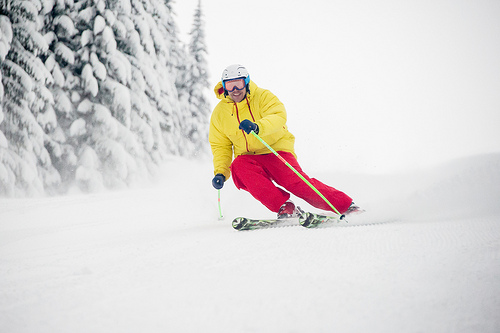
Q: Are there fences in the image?
A: No, there are no fences.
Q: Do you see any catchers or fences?
A: No, there are no fences or catchers.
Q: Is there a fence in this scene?
A: No, there are no fences.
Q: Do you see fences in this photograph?
A: No, there are no fences.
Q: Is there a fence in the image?
A: No, there are no fences.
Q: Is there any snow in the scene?
A: Yes, there is snow.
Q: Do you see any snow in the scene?
A: Yes, there is snow.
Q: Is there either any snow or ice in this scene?
A: Yes, there is snow.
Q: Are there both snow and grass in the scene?
A: No, there is snow but no grass.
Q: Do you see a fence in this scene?
A: No, there are no fences.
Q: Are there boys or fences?
A: No, there are no fences or boys.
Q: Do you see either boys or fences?
A: No, there are no fences or boys.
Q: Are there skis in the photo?
A: Yes, there are skis.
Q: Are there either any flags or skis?
A: Yes, there are skis.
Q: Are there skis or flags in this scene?
A: Yes, there are skis.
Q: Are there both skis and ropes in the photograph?
A: No, there are skis but no ropes.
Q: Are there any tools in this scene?
A: No, there are no tools.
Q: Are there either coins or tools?
A: No, there are no tools or coins.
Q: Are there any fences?
A: No, there are no fences.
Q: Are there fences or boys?
A: No, there are no fences or boys.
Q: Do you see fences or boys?
A: No, there are no fences or boys.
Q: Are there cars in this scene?
A: No, there are no cars.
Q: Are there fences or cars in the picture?
A: No, there are no cars or fences.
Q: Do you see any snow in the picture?
A: Yes, there is snow.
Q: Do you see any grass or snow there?
A: Yes, there is snow.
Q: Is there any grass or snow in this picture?
A: Yes, there is snow.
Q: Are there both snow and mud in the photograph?
A: No, there is snow but no mud.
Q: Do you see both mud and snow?
A: No, there is snow but no mud.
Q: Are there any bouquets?
A: No, there are no bouquets.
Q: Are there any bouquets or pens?
A: No, there are no bouquets or pens.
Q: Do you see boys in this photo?
A: No, there are no boys.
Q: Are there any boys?
A: No, there are no boys.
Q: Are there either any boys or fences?
A: No, there are no boys or fences.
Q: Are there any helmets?
A: Yes, there is a helmet.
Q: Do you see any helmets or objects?
A: Yes, there is a helmet.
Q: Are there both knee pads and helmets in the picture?
A: No, there is a helmet but no knee pads.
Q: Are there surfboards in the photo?
A: No, there are no surfboards.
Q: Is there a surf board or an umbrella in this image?
A: No, there are no surfboards or umbrellas.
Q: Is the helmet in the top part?
A: Yes, the helmet is in the top of the image.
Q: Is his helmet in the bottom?
A: No, the helmet is in the top of the image.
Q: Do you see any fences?
A: No, there are no fences.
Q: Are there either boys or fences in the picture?
A: No, there are no fences or boys.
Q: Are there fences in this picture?
A: No, there are no fences.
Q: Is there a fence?
A: No, there are no fences.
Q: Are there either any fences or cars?
A: No, there are no fences or cars.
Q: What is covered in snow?
A: The tree is covered in snow.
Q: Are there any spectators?
A: No, there are no spectators.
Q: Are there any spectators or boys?
A: No, there are no spectators or boys.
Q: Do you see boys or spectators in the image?
A: No, there are no spectators or boys.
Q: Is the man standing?
A: Yes, the man is standing.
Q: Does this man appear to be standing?
A: Yes, the man is standing.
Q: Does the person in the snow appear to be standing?
A: Yes, the man is standing.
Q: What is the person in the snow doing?
A: The man is standing.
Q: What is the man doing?
A: The man is standing.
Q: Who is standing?
A: The man is standing.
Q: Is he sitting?
A: No, the man is standing.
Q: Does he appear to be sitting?
A: No, the man is standing.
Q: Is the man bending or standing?
A: The man is standing.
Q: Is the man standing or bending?
A: The man is standing.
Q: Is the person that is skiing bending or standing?
A: The man is standing.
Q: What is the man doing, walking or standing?
A: The man is standing.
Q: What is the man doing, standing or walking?
A: The man is standing.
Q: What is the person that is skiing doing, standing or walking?
A: The man is standing.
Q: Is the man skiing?
A: Yes, the man is skiing.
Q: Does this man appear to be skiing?
A: Yes, the man is skiing.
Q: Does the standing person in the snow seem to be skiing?
A: Yes, the man is skiing.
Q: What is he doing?
A: The man is skiing.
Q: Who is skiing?
A: The man is skiing.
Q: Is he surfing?
A: No, the man is skiing.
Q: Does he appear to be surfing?
A: No, the man is skiing.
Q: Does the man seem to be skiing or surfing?
A: The man is skiing.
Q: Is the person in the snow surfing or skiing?
A: The man is skiing.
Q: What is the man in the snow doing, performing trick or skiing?
A: The man is skiing.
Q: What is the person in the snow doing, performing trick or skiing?
A: The man is skiing.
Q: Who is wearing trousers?
A: The man is wearing trousers.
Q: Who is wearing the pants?
A: The man is wearing trousers.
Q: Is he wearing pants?
A: Yes, the man is wearing pants.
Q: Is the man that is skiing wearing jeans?
A: No, the man is wearing pants.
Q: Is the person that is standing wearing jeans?
A: No, the man is wearing pants.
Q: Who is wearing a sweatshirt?
A: The man is wearing a sweatshirt.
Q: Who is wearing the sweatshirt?
A: The man is wearing a sweatshirt.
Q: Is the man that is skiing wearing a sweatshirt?
A: Yes, the man is wearing a sweatshirt.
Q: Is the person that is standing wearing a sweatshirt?
A: Yes, the man is wearing a sweatshirt.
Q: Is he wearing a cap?
A: No, the man is wearing a sweatshirt.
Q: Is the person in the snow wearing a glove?
A: Yes, the man is wearing a glove.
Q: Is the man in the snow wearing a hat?
A: No, the man is wearing a glove.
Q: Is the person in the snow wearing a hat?
A: No, the man is wearing a glove.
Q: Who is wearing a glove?
A: The man is wearing a glove.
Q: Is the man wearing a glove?
A: Yes, the man is wearing a glove.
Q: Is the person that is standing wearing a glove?
A: Yes, the man is wearing a glove.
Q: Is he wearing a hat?
A: No, the man is wearing a glove.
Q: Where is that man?
A: The man is in the snow.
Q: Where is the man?
A: The man is in the snow.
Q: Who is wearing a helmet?
A: The man is wearing a helmet.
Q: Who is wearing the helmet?
A: The man is wearing a helmet.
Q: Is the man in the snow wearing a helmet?
A: Yes, the man is wearing a helmet.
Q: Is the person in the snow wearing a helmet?
A: Yes, the man is wearing a helmet.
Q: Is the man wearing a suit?
A: No, the man is wearing a helmet.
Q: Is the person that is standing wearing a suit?
A: No, the man is wearing a helmet.